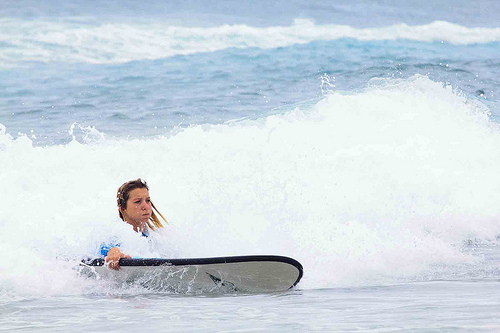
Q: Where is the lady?
A: In the water.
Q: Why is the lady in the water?
A: To surf.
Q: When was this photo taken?
A: Daytime.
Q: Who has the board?
A: The surfer.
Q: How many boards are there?
A: One.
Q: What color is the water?
A: Blue.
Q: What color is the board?
A: White.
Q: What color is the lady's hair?
A: Blonde.